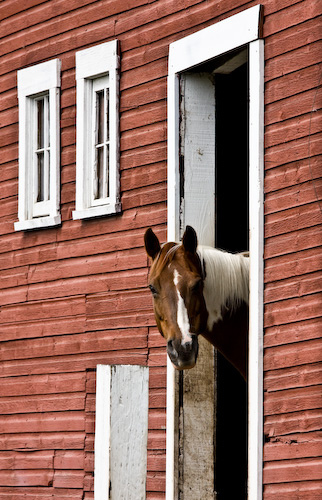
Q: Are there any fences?
A: No, there are no fences.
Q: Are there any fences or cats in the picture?
A: No, there are no fences or cats.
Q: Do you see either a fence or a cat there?
A: No, there are no fences or cats.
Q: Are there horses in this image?
A: Yes, there is a horse.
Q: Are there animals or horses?
A: Yes, there is a horse.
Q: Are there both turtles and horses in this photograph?
A: No, there is a horse but no turtles.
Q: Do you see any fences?
A: No, there are no fences.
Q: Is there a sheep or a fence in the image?
A: No, there are no fences or sheep.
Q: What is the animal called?
A: The animal is a horse.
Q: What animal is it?
A: The animal is a horse.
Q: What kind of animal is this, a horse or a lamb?
A: That is a horse.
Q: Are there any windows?
A: Yes, there is a window.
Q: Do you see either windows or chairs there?
A: Yes, there is a window.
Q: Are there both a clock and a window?
A: No, there is a window but no clocks.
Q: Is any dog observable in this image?
A: No, there are no dogs.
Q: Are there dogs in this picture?
A: No, there are no dogs.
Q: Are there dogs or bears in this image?
A: No, there are no dogs or bears.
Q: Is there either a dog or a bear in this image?
A: No, there are no dogs or bears.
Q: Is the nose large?
A: Yes, the nose is large.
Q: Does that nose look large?
A: Yes, the nose is large.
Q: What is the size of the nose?
A: The nose is large.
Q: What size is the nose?
A: The nose is large.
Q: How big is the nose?
A: The nose is large.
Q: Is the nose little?
A: No, the nose is large.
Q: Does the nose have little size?
A: No, the nose is large.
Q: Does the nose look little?
A: No, the nose is large.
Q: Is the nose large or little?
A: The nose is large.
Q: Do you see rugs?
A: No, there are no rugs.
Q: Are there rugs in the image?
A: No, there are no rugs.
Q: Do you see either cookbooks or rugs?
A: No, there are no rugs or cookbooks.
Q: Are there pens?
A: No, there are no pens.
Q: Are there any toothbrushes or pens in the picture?
A: No, there are no pens or toothbrushes.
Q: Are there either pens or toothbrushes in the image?
A: No, there are no pens or toothbrushes.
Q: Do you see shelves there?
A: No, there are no shelves.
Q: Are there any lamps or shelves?
A: No, there are no shelves or lamps.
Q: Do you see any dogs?
A: No, there are no dogs.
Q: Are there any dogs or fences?
A: No, there are no dogs or fences.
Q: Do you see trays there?
A: No, there are no trays.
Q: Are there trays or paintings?
A: No, there are no trays or paintings.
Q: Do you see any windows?
A: Yes, there is a window.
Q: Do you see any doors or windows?
A: Yes, there is a window.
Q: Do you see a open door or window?
A: Yes, there is an open window.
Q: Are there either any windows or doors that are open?
A: Yes, the window is open.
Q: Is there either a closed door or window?
A: Yes, there is a closed window.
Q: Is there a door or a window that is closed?
A: Yes, the window is closed.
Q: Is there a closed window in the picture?
A: Yes, there is a closed window.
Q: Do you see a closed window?
A: Yes, there is a closed window.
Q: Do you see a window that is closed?
A: Yes, there is a window that is closed.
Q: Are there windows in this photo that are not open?
A: Yes, there is an closed window.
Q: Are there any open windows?
A: Yes, there is an open window.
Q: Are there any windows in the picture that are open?
A: Yes, there is a window that is open.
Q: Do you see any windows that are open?
A: Yes, there is a window that is open.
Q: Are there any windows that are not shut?
A: Yes, there is a open window.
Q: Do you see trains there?
A: No, there are no trains.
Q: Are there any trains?
A: No, there are no trains.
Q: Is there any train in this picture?
A: No, there are no trains.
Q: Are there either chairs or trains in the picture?
A: No, there are no trains or chairs.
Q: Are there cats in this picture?
A: No, there are no cats.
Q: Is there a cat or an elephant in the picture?
A: No, there are no cats or elephants.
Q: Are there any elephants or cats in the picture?
A: No, there are no cats or elephants.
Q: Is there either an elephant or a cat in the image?
A: No, there are no cats or elephants.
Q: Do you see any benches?
A: No, there are no benches.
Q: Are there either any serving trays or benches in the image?
A: No, there are no benches or serving trays.